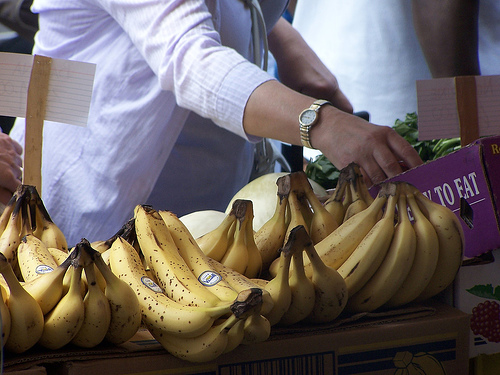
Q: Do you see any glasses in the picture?
A: No, there are no glasses.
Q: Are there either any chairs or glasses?
A: No, there are no glasses or chairs.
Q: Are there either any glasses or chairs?
A: No, there are no glasses or chairs.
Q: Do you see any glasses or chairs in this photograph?
A: No, there are no glasses or chairs.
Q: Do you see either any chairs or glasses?
A: No, there are no glasses or chairs.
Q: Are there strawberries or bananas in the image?
A: Yes, there are bananas.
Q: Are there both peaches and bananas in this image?
A: No, there are bananas but no peaches.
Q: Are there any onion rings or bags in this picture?
A: No, there are no bags or onion rings.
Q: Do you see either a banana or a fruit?
A: Yes, there are bananas.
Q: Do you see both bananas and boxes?
A: Yes, there are both bananas and a box.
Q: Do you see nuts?
A: No, there are no nuts.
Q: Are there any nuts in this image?
A: No, there are no nuts.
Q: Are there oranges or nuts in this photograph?
A: No, there are no nuts or oranges.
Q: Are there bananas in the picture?
A: Yes, there is a banana.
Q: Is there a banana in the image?
A: Yes, there is a banana.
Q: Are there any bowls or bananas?
A: Yes, there is a banana.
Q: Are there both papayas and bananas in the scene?
A: No, there is a banana but no papayas.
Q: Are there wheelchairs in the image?
A: No, there are no wheelchairs.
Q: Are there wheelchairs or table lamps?
A: No, there are no wheelchairs or table lamps.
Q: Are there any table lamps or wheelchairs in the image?
A: No, there are no wheelchairs or table lamps.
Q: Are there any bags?
A: No, there are no bags.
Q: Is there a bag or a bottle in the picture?
A: No, there are no bags or bottles.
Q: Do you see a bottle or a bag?
A: No, there are no bags or bottles.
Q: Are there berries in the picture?
A: Yes, there are berries.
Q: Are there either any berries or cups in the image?
A: Yes, there are berries.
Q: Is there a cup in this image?
A: No, there are no cups.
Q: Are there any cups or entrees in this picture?
A: No, there are no cups or entrees.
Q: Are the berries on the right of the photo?
A: Yes, the berries are on the right of the image.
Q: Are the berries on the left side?
A: No, the berries are on the right of the image.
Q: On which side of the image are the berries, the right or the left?
A: The berries are on the right of the image.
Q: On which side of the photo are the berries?
A: The berries are on the right of the image.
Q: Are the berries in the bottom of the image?
A: Yes, the berries are in the bottom of the image.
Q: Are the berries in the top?
A: No, the berries are in the bottom of the image.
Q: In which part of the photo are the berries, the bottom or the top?
A: The berries are in the bottom of the image.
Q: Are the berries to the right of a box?
A: Yes, the berries are to the right of a box.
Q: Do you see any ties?
A: Yes, there is a tie.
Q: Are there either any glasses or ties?
A: Yes, there is a tie.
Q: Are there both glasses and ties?
A: No, there is a tie but no glasses.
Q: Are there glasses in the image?
A: No, there are no glasses.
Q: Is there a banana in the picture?
A: Yes, there is a banana.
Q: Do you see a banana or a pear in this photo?
A: Yes, there is a banana.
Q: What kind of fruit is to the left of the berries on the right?
A: The fruit is a banana.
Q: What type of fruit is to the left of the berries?
A: The fruit is a banana.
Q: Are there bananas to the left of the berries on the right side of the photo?
A: Yes, there is a banana to the left of the berries.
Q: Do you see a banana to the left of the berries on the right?
A: Yes, there is a banana to the left of the berries.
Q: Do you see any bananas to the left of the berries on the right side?
A: Yes, there is a banana to the left of the berries.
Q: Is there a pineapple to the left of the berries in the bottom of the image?
A: No, there is a banana to the left of the berries.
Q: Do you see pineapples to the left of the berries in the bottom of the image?
A: No, there is a banana to the left of the berries.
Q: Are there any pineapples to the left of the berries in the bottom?
A: No, there is a banana to the left of the berries.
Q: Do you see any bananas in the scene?
A: Yes, there is a banana.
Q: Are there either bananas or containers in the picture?
A: Yes, there is a banana.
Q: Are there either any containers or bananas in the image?
A: Yes, there is a banana.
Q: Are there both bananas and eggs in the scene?
A: No, there is a banana but no eggs.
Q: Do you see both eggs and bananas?
A: No, there is a banana but no eggs.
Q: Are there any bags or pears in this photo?
A: No, there are no bags or pears.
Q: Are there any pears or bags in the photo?
A: No, there are no bags or pears.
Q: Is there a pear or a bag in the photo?
A: No, there are no bags or pears.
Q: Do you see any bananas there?
A: Yes, there is a banana.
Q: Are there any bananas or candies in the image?
A: Yes, there is a banana.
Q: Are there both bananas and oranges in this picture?
A: No, there is a banana but no oranges.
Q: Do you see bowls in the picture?
A: No, there are no bowls.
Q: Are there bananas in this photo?
A: Yes, there are bananas.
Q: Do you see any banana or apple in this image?
A: Yes, there are bananas.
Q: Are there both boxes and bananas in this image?
A: Yes, there are both bananas and a box.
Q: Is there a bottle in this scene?
A: No, there are no bottles.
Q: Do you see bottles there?
A: No, there are no bottles.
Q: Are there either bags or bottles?
A: No, there are no bottles or bags.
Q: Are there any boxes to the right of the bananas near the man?
A: Yes, there is a box to the right of the bananas.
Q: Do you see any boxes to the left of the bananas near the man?
A: No, the box is to the right of the bananas.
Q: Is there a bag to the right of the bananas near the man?
A: No, there is a box to the right of the bananas.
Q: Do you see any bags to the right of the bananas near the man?
A: No, there is a box to the right of the bananas.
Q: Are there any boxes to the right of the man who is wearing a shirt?
A: Yes, there is a box to the right of the man.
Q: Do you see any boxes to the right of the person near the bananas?
A: Yes, there is a box to the right of the man.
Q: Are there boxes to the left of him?
A: No, the box is to the right of the man.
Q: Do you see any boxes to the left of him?
A: No, the box is to the right of the man.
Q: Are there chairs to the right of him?
A: No, there is a box to the right of the man.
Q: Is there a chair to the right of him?
A: No, there is a box to the right of the man.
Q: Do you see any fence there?
A: No, there are no fences.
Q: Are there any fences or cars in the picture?
A: No, there are no fences or cars.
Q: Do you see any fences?
A: No, there are no fences.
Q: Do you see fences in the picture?
A: No, there are no fences.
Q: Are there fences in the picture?
A: No, there are no fences.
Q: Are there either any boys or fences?
A: No, there are no fences or boys.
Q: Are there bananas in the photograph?
A: Yes, there are bananas.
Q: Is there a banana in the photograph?
A: Yes, there are bananas.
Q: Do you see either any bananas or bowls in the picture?
A: Yes, there are bananas.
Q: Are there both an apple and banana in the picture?
A: No, there are bananas but no apples.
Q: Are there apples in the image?
A: No, there are no apples.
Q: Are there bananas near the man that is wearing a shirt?
A: Yes, there are bananas near the man.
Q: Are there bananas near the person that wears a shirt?
A: Yes, there are bananas near the man.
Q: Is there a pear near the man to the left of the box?
A: No, there are bananas near the man.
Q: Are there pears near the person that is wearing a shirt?
A: No, there are bananas near the man.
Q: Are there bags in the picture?
A: No, there are no bags.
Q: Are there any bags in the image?
A: No, there are no bags.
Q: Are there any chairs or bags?
A: No, there are no bags or chairs.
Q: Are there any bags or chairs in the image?
A: No, there are no bags or chairs.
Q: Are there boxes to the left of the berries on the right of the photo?
A: Yes, there is a box to the left of the berries.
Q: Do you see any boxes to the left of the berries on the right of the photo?
A: Yes, there is a box to the left of the berries.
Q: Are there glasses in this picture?
A: No, there are no glasses.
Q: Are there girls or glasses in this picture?
A: No, there are no glasses or girls.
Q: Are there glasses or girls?
A: No, there are no glasses or girls.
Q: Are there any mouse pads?
A: No, there are no mouse pads.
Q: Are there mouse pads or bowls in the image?
A: No, there are no mouse pads or bowls.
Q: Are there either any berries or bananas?
A: Yes, there is a banana.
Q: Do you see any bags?
A: No, there are no bags.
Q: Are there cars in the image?
A: No, there are no cars.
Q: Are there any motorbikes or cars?
A: No, there are no cars or motorbikes.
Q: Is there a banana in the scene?
A: Yes, there are bananas.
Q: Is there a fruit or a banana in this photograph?
A: Yes, there are bananas.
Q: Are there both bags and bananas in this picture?
A: No, there are bananas but no bags.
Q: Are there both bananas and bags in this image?
A: No, there are bananas but no bags.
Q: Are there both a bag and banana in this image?
A: No, there are bananas but no bags.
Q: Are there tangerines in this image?
A: No, there are no tangerines.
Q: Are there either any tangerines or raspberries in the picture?
A: No, there are no tangerines or raspberries.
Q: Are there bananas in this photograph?
A: Yes, there are bananas.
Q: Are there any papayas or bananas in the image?
A: Yes, there are bananas.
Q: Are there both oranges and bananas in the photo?
A: No, there are bananas but no oranges.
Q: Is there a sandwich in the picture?
A: No, there are no sandwiches.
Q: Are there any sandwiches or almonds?
A: No, there are no sandwiches or almonds.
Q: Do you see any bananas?
A: Yes, there is a banana.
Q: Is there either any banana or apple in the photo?
A: Yes, there is a banana.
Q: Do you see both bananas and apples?
A: No, there is a banana but no apples.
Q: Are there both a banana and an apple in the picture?
A: No, there is a banana but no apples.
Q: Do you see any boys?
A: No, there are no boys.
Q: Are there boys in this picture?
A: No, there are no boys.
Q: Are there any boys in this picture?
A: No, there are no boys.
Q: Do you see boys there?
A: No, there are no boys.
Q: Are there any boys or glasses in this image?
A: No, there are no boys or glasses.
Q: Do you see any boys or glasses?
A: No, there are no boys or glasses.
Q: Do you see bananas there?
A: Yes, there are bananas.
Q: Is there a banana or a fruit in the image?
A: Yes, there are bananas.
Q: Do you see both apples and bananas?
A: No, there are bananas but no apples.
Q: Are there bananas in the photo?
A: Yes, there are bananas.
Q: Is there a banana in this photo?
A: Yes, there are bananas.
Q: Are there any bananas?
A: Yes, there are bananas.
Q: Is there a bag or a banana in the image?
A: Yes, there are bananas.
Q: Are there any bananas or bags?
A: Yes, there are bananas.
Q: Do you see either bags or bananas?
A: Yes, there are bananas.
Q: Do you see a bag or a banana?
A: Yes, there are bananas.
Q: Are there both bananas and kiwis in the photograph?
A: No, there are bananas but no kiwis.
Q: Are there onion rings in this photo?
A: No, there are no onion rings.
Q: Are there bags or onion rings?
A: No, there are no onion rings or bags.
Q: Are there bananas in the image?
A: Yes, there is a banana.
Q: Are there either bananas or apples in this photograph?
A: Yes, there is a banana.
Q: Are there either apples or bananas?
A: Yes, there is a banana.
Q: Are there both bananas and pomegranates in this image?
A: No, there is a banana but no pomegranates.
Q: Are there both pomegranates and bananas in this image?
A: No, there is a banana but no pomegranates.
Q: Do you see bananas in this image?
A: Yes, there is a banana.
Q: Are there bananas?
A: Yes, there is a banana.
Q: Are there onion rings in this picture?
A: No, there are no onion rings.